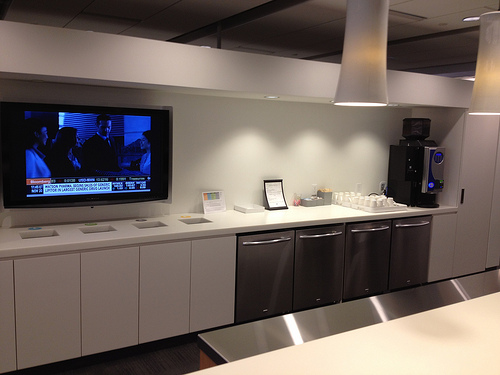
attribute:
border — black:
[0, 96, 179, 208]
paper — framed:
[263, 180, 285, 207]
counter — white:
[0, 180, 455, 270]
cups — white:
[352, 190, 397, 221]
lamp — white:
[333, 0, 391, 115]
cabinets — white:
[5, 233, 235, 363]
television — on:
[4, 103, 173, 203]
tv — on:
[10, 104, 180, 205]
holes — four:
[12, 214, 257, 236]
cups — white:
[388, 198, 393, 204]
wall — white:
[182, 118, 242, 163]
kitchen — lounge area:
[7, 267, 492, 373]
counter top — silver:
[197, 267, 499, 363]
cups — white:
[332, 189, 397, 214]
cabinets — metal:
[235, 214, 433, 324]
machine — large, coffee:
[388, 114, 441, 210]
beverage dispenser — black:
[386, 117, 445, 208]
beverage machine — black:
[383, 117, 448, 207]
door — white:
[439, 102, 484, 262]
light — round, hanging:
[326, 0, 388, 107]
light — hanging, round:
[463, 10, 498, 120]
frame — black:
[261, 178, 286, 211]